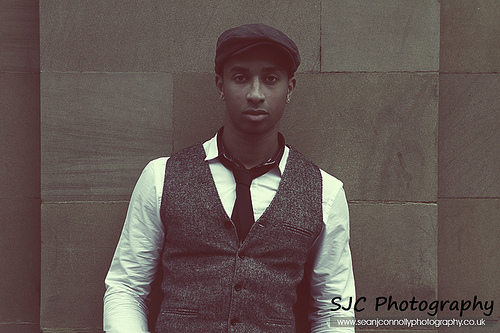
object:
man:
[101, 20, 362, 332]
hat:
[212, 22, 302, 74]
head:
[212, 24, 301, 132]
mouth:
[242, 106, 269, 120]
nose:
[249, 76, 267, 102]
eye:
[263, 73, 279, 87]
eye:
[230, 73, 248, 85]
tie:
[218, 155, 275, 239]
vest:
[158, 144, 326, 328]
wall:
[39, 1, 499, 331]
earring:
[287, 96, 293, 104]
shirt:
[103, 136, 361, 332]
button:
[237, 248, 247, 260]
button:
[232, 280, 246, 293]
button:
[229, 315, 240, 327]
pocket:
[280, 220, 314, 238]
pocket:
[157, 304, 199, 318]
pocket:
[264, 311, 298, 328]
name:
[328, 293, 496, 313]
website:
[332, 317, 489, 329]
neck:
[219, 132, 285, 163]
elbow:
[100, 273, 153, 302]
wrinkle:
[111, 273, 153, 287]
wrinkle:
[108, 290, 147, 299]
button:
[222, 216, 236, 230]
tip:
[204, 154, 212, 165]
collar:
[205, 133, 220, 163]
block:
[42, 73, 177, 201]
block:
[171, 71, 440, 202]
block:
[41, 200, 129, 327]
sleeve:
[101, 161, 162, 331]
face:
[222, 54, 288, 133]